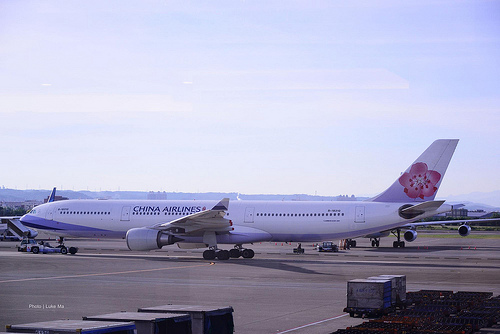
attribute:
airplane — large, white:
[19, 136, 460, 265]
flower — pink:
[401, 162, 442, 198]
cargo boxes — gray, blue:
[346, 274, 407, 310]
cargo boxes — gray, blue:
[9, 304, 235, 334]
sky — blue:
[1, 1, 499, 193]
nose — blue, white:
[18, 214, 38, 229]